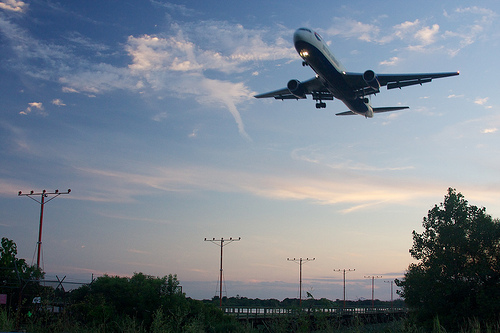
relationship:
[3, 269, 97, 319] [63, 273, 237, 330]
fence behind bushes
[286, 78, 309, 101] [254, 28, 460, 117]
engine of airplane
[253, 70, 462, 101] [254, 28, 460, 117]
wingspan of airplane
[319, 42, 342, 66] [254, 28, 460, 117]
windows on airplane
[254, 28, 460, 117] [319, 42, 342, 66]
airplane has windows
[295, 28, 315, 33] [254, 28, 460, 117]
windshield of airplane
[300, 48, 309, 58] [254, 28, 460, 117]
light on airplane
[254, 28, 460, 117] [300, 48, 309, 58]
airplane with light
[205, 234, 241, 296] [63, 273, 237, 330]
pole behind bushes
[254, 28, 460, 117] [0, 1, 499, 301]
airplane in sky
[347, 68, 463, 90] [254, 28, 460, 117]
wing of airplane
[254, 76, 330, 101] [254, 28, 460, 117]
wing of airplane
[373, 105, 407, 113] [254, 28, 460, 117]
tail wing of airplane